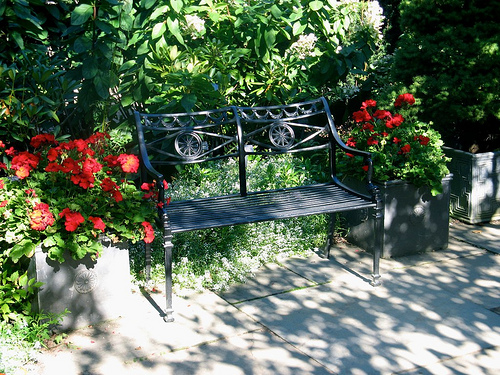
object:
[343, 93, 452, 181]
rose bush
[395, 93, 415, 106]
flower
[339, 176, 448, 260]
garden box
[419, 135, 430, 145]
flower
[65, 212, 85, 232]
flower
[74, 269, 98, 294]
design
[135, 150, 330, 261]
bush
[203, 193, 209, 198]
flower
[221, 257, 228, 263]
flower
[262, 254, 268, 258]
flower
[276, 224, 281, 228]
flower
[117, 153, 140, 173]
flower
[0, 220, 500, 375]
sidewalk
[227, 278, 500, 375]
stone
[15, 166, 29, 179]
flower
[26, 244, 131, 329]
garden box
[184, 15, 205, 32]
flowers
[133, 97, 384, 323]
bench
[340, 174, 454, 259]
box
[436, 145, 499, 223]
box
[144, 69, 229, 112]
plants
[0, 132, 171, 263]
bush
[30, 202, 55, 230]
flower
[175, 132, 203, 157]
wheel